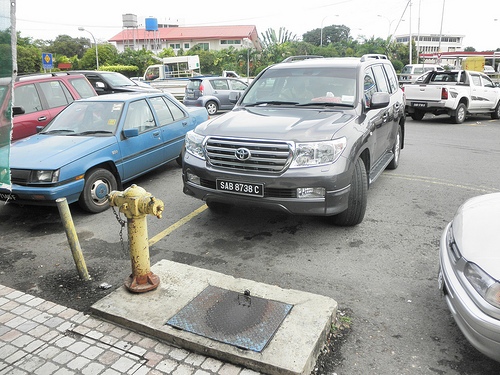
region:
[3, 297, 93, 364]
white and pinkish white square tiles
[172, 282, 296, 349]
blue metal square manhole cover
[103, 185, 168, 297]
yellow metal fire hydrant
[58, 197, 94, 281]
faded yellow concrete car stop pole at angle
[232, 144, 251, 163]
stylized vehicle logo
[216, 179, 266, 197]
license plate reading SAB 8738 C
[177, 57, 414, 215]
dark grey SUV type vehicle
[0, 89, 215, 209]
blue passenger automobile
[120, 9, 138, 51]
grey water tower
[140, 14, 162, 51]
blue water tower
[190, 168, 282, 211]
car has black license plate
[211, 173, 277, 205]
license plate with white writing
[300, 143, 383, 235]
car has wheel turned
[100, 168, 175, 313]
fire hydrant is yellow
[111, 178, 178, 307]
fire hydrant has rust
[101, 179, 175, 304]
fire hydrant has chain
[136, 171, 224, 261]
yellow line painted on ground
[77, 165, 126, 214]
car has blue hubcap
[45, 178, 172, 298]
yellow pole next to fire hydrant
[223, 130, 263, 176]
car symbol is silver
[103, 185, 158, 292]
Yellow fire hydrant in the ground.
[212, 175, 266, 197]
Black and white car tag.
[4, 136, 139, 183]
Blue vehicle parked net to truck.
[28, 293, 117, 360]
Brick sidewalk next to parking lot.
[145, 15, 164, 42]
Blue water statue in the background.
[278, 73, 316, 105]
Man sitting in the front of the car.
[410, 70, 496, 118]
White truck with black marks on it.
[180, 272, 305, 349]
Thing in the ground for sewage.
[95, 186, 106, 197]
Blue hubcap on the tire.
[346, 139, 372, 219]
Turned tire in the parking lot.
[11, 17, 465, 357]
picture taken outdoors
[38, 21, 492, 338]
picture taken during the day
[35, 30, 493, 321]
cars in a parking lot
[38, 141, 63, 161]
the car is blue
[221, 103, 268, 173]
the car is a toyota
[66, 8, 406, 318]
the car is behind a fire hydrant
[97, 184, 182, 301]
the hydrant is yellow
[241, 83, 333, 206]
the car is black in color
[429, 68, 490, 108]
the truck is white in color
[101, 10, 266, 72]
buildings in the background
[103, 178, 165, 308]
a yellow fire hydrant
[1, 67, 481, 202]
several cars parked in a lot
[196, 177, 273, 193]
a black tag with white letters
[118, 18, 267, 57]
a building with a red roof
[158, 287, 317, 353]
a metal access panel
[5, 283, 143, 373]
a white brick side walk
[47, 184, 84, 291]
a yellow post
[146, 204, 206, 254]
a yellow line painted on pavement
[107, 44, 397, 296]
a car parked next to a fire hydrant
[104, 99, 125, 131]
stickers in a windshield of a car